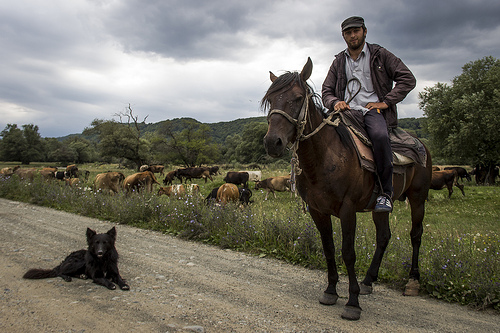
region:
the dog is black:
[35, 198, 185, 305]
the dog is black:
[54, 238, 144, 323]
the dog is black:
[13, 196, 88, 306]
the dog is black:
[4, 111, 199, 324]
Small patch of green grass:
[453, 200, 464, 211]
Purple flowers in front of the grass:
[187, 216, 203, 232]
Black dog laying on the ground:
[37, 224, 135, 297]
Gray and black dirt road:
[144, 300, 166, 322]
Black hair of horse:
[276, 72, 294, 88]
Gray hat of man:
[339, 14, 366, 29]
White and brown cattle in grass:
[161, 183, 201, 203]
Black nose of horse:
[258, 132, 288, 157]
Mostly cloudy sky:
[87, 5, 247, 99]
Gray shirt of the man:
[353, 62, 367, 78]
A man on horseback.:
[176, 7, 462, 330]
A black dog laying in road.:
[3, 203, 161, 298]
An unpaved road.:
[11, 204, 297, 331]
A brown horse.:
[265, 62, 456, 329]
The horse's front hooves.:
[318, 260, 367, 329]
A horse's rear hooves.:
[351, 247, 427, 300]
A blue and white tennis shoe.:
[320, 14, 430, 214]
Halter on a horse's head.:
[239, 57, 339, 163]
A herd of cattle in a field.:
[10, 125, 316, 217]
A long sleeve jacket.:
[315, 37, 420, 130]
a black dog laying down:
[20, 225, 131, 293]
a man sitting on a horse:
[257, 10, 432, 325]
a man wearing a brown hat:
[320, 12, 415, 222]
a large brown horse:
[252, 55, 432, 321]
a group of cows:
[2, 152, 472, 217]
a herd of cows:
[0, 157, 472, 212]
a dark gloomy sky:
[0, 0, 496, 137]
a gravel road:
[0, 197, 495, 327]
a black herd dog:
[20, 221, 130, 287]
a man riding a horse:
[260, 13, 430, 321]